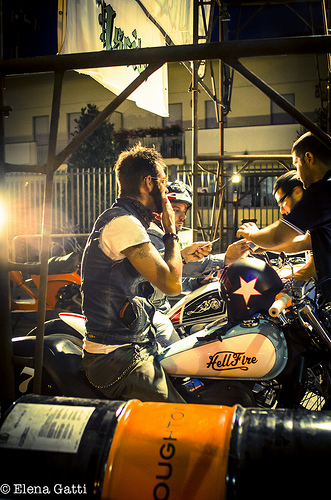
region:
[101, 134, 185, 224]
Man with brown hair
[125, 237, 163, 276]
man with a tattoo on his arm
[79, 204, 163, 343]
man wearing a jean jacket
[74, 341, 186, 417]
man wearing gray pants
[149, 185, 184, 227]
man with his hand on his face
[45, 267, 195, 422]
man sitting on a motorcycle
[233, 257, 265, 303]
star on the side of a helmet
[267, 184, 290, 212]
man wearing reading glasses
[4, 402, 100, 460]
white sticker on a barrel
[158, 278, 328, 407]
Blue and white motorcycle.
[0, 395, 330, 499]
Black and orange drum.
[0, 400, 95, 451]
Black and white paper.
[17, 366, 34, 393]
A white number seven.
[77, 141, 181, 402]
A man wearing a vest.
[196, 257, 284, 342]
A black motorcycle helmet.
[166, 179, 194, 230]
Man wearing a helmet.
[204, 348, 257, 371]
Black lettering on white.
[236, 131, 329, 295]
Man wearing a black shirt.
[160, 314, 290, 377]
gas tank of the motorcycle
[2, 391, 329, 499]
55 gallon drum on its side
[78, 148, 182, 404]
a man on a motorcycle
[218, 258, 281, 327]
helmet with a single star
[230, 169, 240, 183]
a shop light hanging up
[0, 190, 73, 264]
glare from a light on the left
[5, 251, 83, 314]
an orange motor bike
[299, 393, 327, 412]
light visible between spokes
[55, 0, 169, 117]
a banner above the room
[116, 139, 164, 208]
boy has brown hair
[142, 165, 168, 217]
boy has thick beard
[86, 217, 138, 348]
boy has white shirt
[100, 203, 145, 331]
boy has blue vest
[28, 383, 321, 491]
black and orange barrel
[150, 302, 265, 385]
white and blue bike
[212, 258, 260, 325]
black helmet on bike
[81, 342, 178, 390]
boy has black pants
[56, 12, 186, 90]
green and white flag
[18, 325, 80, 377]
black seat on bike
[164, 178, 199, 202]
a motorcycle helmet on the man's head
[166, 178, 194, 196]
goggles on top of the motorcycle helmet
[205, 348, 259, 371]
a logo that says HellFire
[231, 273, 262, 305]
a white star on the side of the helmet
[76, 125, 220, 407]
two men sitting on motorcycles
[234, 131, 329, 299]
men exchanging information with the motorcyclists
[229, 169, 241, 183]
a light on the building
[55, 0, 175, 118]
a banner above the motorcyclists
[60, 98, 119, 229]
a tree in front of the building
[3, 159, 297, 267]
a fence behind the motorcyclists